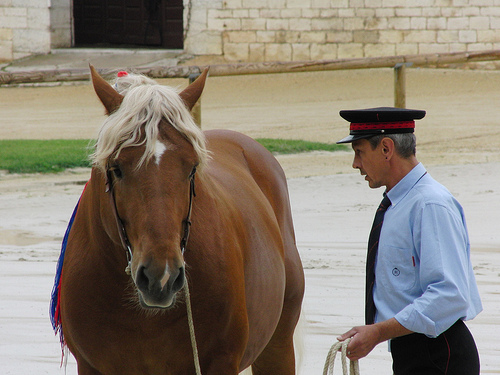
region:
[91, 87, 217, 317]
face of the horse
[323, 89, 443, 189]
face of a person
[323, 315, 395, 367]
hand of the person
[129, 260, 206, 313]
nose of the horse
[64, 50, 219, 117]
ears of the horse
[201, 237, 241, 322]
brown skin of horse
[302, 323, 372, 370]
a white thread on man hand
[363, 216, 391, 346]
a black tie wearing by person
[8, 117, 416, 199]
a beautiful green grass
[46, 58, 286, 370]
Brown horse standing by the man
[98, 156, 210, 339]
Bridle on horses face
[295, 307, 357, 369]
Man holding a white rope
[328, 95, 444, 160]
Man wearing a conductor hat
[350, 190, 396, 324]
Man wearing a tie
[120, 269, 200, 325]
Hair coming off horses face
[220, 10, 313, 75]
Bricks on the wall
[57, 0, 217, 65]
Doorway on the brick wall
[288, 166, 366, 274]
Sand on the ground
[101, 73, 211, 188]
The horse has a blonde mane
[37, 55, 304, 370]
large silky brown horse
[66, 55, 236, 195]
white hair on horse head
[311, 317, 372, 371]
hand holding horse leading rope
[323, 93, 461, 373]
man in uniform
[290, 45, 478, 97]
wooden fence enclosure in background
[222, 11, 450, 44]
dirty white stone wall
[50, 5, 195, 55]
open doorway in stone wall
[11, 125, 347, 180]
patch of green grass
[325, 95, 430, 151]
red and black uniform cap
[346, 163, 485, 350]
light blue button down shirt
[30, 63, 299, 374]
horse in the foreground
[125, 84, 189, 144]
white hair on horse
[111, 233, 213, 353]
nose of the horse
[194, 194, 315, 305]
body of the horse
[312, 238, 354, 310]
ground below the horse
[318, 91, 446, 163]
hat on the man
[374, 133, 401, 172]
ear of the man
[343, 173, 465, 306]
shirt on the man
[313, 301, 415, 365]
hand of the man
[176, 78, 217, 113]
ear of the horse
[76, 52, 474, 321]
man in blue shirt talking to horse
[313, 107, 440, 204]
man in blue shirt wearing cap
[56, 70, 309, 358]
large round brown horse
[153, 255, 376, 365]
man has rope around horse's bridle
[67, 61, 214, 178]
horse has blond forelock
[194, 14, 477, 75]
white brick wall in distance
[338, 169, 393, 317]
man in blue shirt wearing tie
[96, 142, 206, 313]
horse wearing bridle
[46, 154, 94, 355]
red and blue blanket on horse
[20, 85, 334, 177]
small patch of green grass in background